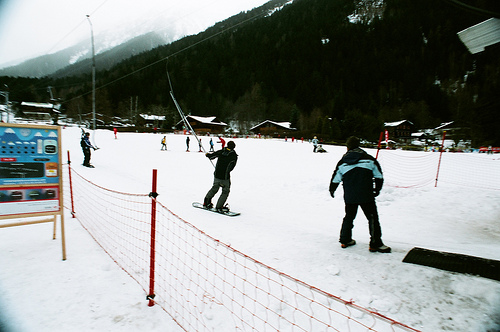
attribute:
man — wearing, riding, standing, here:
[327, 146, 401, 258]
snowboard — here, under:
[182, 196, 242, 223]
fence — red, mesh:
[120, 183, 190, 259]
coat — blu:
[313, 149, 383, 186]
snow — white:
[115, 150, 184, 188]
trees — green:
[240, 59, 341, 121]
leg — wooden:
[423, 242, 471, 276]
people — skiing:
[138, 118, 258, 174]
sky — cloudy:
[83, 4, 151, 35]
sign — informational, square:
[15, 139, 68, 205]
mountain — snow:
[269, 22, 415, 113]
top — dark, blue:
[197, 151, 249, 171]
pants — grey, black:
[208, 182, 246, 211]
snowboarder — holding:
[203, 137, 247, 224]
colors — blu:
[329, 148, 371, 172]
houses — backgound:
[453, 32, 485, 71]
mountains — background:
[216, 22, 453, 111]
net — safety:
[67, 164, 127, 230]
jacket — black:
[327, 167, 375, 198]